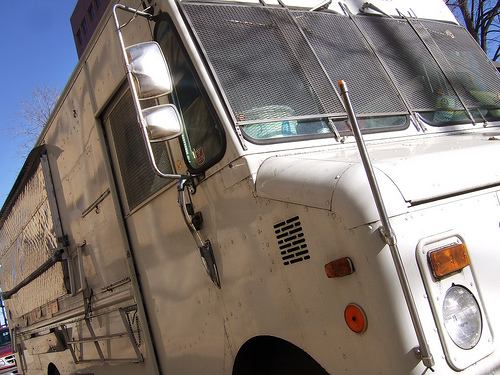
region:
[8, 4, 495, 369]
a large white van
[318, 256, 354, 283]
a vehicle turn signal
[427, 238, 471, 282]
a vehicle turn signal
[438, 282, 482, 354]
a vehicle turn headlight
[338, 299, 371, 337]
a vehicle reflector circle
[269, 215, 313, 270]
a cutout metal vent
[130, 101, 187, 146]
a rear view mirror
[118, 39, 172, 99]
a rear view mirror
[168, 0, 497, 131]
metal screen windshield protector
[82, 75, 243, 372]
white sliding side door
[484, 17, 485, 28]
branch of a tree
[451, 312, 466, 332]
light of a truck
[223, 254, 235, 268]
edge of a bus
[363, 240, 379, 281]
front part of a bus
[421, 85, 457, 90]
window of a bus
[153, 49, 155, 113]
side mirror of a truck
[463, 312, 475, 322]
front light of a truck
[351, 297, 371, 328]
side light of a truck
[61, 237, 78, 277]
edge of a truck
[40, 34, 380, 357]
white roach coach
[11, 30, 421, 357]
white food truck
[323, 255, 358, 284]
amber light on truck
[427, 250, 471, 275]
amber light on truck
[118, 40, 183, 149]
mirror of food truck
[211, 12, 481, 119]
windshield of food truck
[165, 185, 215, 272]
metal handle of door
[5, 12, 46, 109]
blue sky without clouds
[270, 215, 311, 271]
side vent on food truck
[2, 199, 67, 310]
metal window of food truck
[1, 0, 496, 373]
food truck, presently out of service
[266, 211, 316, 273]
some sort of instructions printed on food truck, unintelligible in picture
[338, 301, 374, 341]
round orange reflector on side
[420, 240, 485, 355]
pushed in round white headlight, poked out rectangular orange head/brakelight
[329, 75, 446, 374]
long orange-tip pole @ front of food truck, but for what?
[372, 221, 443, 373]
orange-tip pole held but silvertone brackets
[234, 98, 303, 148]
pale colour bucket of something, in window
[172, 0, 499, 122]
chain mesh windscreen-wide visor on windscreen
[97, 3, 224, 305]
huge bracket for holding dual side mirrors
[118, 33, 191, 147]
dual side mirrors, one long, one slightly short, both rectangular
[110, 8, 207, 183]
The sun is on the mirror.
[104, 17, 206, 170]
The mirror is metal.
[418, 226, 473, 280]
The light is orange.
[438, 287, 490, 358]
The light is white.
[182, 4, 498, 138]
The windshield is clear.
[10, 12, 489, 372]
The truck is white.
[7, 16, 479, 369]
The truck is close up.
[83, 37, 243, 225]
The window is on the side.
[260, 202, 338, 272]
The vent is on the truck.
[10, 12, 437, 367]
The sun is shinging on the truck.